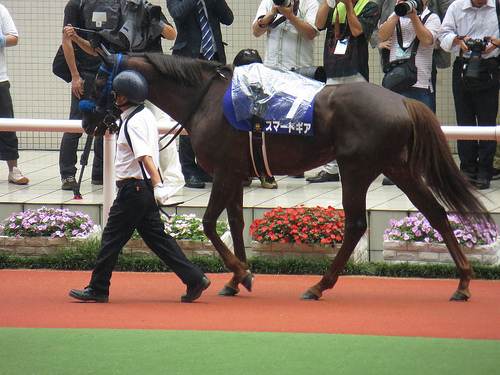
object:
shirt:
[115, 99, 161, 181]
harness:
[77, 52, 120, 128]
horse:
[82, 43, 472, 300]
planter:
[248, 238, 368, 252]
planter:
[3, 234, 103, 254]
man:
[69, 70, 210, 302]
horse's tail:
[403, 92, 497, 229]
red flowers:
[244, 196, 344, 253]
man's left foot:
[68, 286, 109, 304]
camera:
[271, 0, 297, 14]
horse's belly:
[248, 130, 273, 178]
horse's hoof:
[301, 290, 319, 301]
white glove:
[155, 183, 175, 207]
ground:
[1, 264, 499, 344]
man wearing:
[86, 177, 204, 289]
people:
[0, 1, 29, 184]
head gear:
[111, 70, 149, 105]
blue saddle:
[222, 62, 324, 136]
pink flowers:
[9, 206, 87, 238]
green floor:
[0, 326, 499, 371]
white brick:
[6, 7, 283, 165]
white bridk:
[3, 2, 421, 134]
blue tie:
[194, 1, 216, 61]